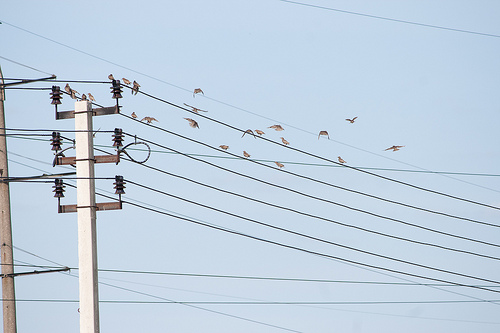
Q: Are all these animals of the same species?
A: Yes, all the animals are birds.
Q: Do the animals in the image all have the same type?
A: Yes, all the animals are birds.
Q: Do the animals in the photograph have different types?
A: No, all the animals are birds.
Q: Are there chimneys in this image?
A: No, there are no chimneys.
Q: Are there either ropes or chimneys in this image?
A: No, there are no chimneys or ropes.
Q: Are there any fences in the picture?
A: No, there are no fences.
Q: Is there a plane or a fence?
A: No, there are no fences or airplanes.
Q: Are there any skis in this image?
A: No, there are no skis.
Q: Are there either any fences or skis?
A: No, there are no skis or fences.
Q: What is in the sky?
A: The clouds are in the sky.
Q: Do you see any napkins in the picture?
A: No, there are no napkins.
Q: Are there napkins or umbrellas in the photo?
A: No, there are no napkins or umbrellas.